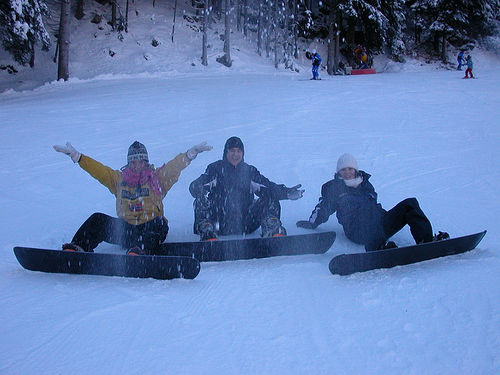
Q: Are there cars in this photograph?
A: No, there are no cars.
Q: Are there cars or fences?
A: No, there are no cars or fences.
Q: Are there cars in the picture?
A: No, there are no cars.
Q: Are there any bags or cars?
A: No, there are no cars or bags.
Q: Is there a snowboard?
A: Yes, there is a snowboard.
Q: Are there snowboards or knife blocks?
A: Yes, there is a snowboard.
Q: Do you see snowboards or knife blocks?
A: Yes, there is a snowboard.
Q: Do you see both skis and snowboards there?
A: No, there is a snowboard but no skis.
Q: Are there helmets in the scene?
A: No, there are no helmets.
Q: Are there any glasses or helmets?
A: No, there are no helmets or glasses.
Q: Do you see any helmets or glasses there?
A: No, there are no helmets or glasses.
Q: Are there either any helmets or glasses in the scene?
A: No, there are no helmets or glasses.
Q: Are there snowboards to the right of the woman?
A: Yes, there is a snowboard to the right of the woman.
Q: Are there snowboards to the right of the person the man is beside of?
A: Yes, there is a snowboard to the right of the woman.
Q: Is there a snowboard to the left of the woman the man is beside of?
A: No, the snowboard is to the right of the woman.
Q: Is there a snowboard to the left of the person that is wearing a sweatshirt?
A: No, the snowboard is to the right of the woman.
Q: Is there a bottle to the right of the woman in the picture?
A: No, there is a snowboard to the right of the woman.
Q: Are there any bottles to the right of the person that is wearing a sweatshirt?
A: No, there is a snowboard to the right of the woman.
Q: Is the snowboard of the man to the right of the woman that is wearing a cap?
A: Yes, the snowboard is to the right of the woman.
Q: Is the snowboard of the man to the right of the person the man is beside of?
A: Yes, the snowboard is to the right of the woman.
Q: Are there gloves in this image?
A: Yes, there are gloves.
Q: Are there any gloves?
A: Yes, there are gloves.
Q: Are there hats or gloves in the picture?
A: Yes, there are gloves.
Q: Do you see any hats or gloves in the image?
A: Yes, there are gloves.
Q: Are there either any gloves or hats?
A: Yes, there are gloves.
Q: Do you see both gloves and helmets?
A: No, there are gloves but no helmets.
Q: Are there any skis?
A: No, there are no skis.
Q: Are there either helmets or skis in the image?
A: No, there are no skis or helmets.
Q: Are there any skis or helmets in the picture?
A: No, there are no skis or helmets.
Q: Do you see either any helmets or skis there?
A: No, there are no skis or helmets.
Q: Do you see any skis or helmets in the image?
A: No, there are no skis or helmets.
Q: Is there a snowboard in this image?
A: Yes, there is a snowboard.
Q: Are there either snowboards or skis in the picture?
A: Yes, there is a snowboard.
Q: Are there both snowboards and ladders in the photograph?
A: No, there is a snowboard but no ladders.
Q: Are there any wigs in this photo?
A: No, there are no wigs.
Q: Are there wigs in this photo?
A: No, there are no wigs.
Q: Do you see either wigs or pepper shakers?
A: No, there are no wigs or pepper shakers.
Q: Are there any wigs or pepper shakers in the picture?
A: No, there are no wigs or pepper shakers.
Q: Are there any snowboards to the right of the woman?
A: Yes, there is a snowboard to the right of the woman.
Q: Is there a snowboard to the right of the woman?
A: Yes, there is a snowboard to the right of the woman.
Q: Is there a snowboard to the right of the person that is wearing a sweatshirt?
A: Yes, there is a snowboard to the right of the woman.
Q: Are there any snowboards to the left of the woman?
A: No, the snowboard is to the right of the woman.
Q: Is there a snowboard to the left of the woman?
A: No, the snowboard is to the right of the woman.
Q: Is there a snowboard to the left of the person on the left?
A: No, the snowboard is to the right of the woman.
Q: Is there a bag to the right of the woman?
A: No, there is a snowboard to the right of the woman.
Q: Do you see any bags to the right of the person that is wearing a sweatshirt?
A: No, there is a snowboard to the right of the woman.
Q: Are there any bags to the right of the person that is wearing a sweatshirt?
A: No, there is a snowboard to the right of the woman.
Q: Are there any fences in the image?
A: No, there are no fences.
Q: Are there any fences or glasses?
A: No, there are no fences or glasses.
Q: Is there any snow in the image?
A: Yes, there is snow.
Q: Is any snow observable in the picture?
A: Yes, there is snow.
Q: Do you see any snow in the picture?
A: Yes, there is snow.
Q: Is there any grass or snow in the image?
A: Yes, there is snow.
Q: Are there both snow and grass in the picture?
A: No, there is snow but no grass.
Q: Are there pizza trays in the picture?
A: No, there are no pizza trays.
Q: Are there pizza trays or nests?
A: No, there are no pizza trays or nests.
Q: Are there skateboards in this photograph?
A: No, there are no skateboards.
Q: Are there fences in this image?
A: No, there are no fences.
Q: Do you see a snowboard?
A: Yes, there is a snowboard.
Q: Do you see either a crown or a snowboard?
A: Yes, there is a snowboard.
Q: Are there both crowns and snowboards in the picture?
A: No, there is a snowboard but no crowns.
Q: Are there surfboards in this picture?
A: No, there are no surfboards.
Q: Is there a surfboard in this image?
A: No, there are no surfboards.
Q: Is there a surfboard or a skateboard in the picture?
A: No, there are no surfboards or skateboards.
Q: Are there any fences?
A: No, there are no fences.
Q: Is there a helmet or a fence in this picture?
A: No, there are no fences or helmets.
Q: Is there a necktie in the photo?
A: No, there are no ties.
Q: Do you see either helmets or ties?
A: No, there are no ties or helmets.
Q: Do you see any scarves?
A: Yes, there is a scarf.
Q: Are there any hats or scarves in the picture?
A: Yes, there is a scarf.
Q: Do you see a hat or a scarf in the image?
A: Yes, there is a scarf.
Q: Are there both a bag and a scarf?
A: No, there is a scarf but no bags.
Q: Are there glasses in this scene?
A: No, there are no glasses.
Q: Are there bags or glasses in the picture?
A: No, there are no glasses or bags.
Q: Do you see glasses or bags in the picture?
A: No, there are no glasses or bags.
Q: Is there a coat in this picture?
A: Yes, there is a coat.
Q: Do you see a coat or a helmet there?
A: Yes, there is a coat.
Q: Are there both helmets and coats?
A: No, there is a coat but no helmets.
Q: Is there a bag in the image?
A: No, there are no bags.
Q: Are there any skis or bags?
A: No, there are no bags or skis.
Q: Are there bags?
A: No, there are no bags.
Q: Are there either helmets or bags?
A: No, there are no bags or helmets.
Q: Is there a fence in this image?
A: No, there are no fences.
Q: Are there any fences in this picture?
A: No, there are no fences.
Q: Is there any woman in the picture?
A: Yes, there is a woman.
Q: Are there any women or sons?
A: Yes, there is a woman.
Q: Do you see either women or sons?
A: Yes, there is a woman.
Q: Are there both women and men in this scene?
A: Yes, there are both a woman and a man.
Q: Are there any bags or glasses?
A: No, there are no bags or glasses.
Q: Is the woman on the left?
A: Yes, the woman is on the left of the image.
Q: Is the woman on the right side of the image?
A: No, the woman is on the left of the image.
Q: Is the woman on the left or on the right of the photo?
A: The woman is on the left of the image.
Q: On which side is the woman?
A: The woman is on the left of the image.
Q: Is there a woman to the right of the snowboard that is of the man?
A: No, the woman is to the left of the snowboard.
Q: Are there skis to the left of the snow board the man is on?
A: No, there is a woman to the left of the snowboard.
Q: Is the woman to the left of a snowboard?
A: Yes, the woman is to the left of a snowboard.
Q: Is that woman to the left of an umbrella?
A: No, the woman is to the left of a snowboard.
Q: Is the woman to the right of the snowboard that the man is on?
A: No, the woman is to the left of the snowboard.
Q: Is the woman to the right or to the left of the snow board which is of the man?
A: The woman is to the left of the snowboard.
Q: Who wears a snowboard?
A: The woman wears a snowboard.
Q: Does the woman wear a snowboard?
A: Yes, the woman wears a snowboard.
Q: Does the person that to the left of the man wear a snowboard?
A: Yes, the woman wears a snowboard.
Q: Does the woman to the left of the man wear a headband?
A: No, the woman wears a snowboard.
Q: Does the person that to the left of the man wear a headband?
A: No, the woman wears a snowboard.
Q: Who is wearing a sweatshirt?
A: The woman is wearing a sweatshirt.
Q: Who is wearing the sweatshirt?
A: The woman is wearing a sweatshirt.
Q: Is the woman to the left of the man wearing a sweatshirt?
A: Yes, the woman is wearing a sweatshirt.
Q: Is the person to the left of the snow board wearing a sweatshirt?
A: Yes, the woman is wearing a sweatshirt.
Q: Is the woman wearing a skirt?
A: No, the woman is wearing a sweatshirt.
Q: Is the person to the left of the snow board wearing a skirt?
A: No, the woman is wearing a sweatshirt.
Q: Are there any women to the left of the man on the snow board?
A: Yes, there is a woman to the left of the man.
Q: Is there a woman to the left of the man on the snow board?
A: Yes, there is a woman to the left of the man.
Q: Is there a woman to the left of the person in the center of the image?
A: Yes, there is a woman to the left of the man.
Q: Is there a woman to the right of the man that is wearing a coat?
A: No, the woman is to the left of the man.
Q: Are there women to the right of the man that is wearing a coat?
A: No, the woman is to the left of the man.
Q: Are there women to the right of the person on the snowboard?
A: No, the woman is to the left of the man.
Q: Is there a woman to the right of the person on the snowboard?
A: No, the woman is to the left of the man.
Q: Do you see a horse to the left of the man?
A: No, there is a woman to the left of the man.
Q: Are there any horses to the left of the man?
A: No, there is a woman to the left of the man.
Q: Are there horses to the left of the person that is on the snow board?
A: No, there is a woman to the left of the man.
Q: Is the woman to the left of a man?
A: Yes, the woman is to the left of a man.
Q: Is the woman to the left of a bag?
A: No, the woman is to the left of a man.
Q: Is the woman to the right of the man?
A: No, the woman is to the left of the man.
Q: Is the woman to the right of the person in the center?
A: No, the woman is to the left of the man.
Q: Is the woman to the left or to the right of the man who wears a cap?
A: The woman is to the left of the man.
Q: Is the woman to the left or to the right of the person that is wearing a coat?
A: The woman is to the left of the man.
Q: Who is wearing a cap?
A: The woman is wearing a cap.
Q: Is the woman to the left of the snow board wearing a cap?
A: Yes, the woman is wearing a cap.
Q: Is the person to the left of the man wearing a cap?
A: Yes, the woman is wearing a cap.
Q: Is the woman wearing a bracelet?
A: No, the woman is wearing a cap.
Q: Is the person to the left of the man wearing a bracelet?
A: No, the woman is wearing a cap.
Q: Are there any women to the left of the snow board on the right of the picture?
A: Yes, there is a woman to the left of the snowboard.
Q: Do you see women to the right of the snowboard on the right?
A: No, the woman is to the left of the snowboard.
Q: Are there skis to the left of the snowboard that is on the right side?
A: No, there is a woman to the left of the snow board.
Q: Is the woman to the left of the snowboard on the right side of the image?
A: Yes, the woman is to the left of the snowboard.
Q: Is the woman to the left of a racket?
A: No, the woman is to the left of the snowboard.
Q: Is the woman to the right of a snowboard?
A: No, the woman is to the left of a snowboard.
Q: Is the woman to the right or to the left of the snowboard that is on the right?
A: The woman is to the left of the snow board.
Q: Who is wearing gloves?
A: The woman is wearing gloves.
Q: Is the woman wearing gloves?
A: Yes, the woman is wearing gloves.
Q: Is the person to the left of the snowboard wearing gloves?
A: Yes, the woman is wearing gloves.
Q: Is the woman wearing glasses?
A: No, the woman is wearing gloves.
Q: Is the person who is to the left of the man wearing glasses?
A: No, the woman is wearing gloves.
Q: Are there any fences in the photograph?
A: No, there are no fences.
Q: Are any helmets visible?
A: No, there are no helmets.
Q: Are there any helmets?
A: No, there are no helmets.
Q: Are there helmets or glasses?
A: No, there are no helmets or glasses.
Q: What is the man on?
A: The man is on the snow board.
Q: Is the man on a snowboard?
A: Yes, the man is on a snowboard.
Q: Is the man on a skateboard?
A: No, the man is on a snowboard.